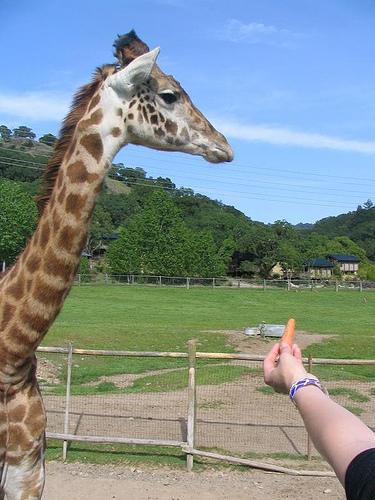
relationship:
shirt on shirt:
[345, 447, 375, 500] [347, 444, 374, 495]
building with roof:
[303, 256, 335, 277] [302, 252, 359, 264]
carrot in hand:
[277, 317, 304, 352] [260, 338, 305, 390]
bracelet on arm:
[289, 377, 329, 402] [264, 341, 373, 495]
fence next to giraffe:
[34, 345, 374, 476] [3, 22, 240, 498]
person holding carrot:
[259, 342, 374, 498] [276, 312, 299, 348]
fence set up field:
[162, 261, 374, 295] [67, 284, 375, 438]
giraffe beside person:
[3, 22, 240, 498] [256, 312, 374, 498]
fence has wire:
[35, 344, 374, 469] [75, 358, 179, 434]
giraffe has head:
[3, 22, 240, 498] [99, 29, 237, 177]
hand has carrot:
[259, 328, 374, 458] [278, 315, 296, 347]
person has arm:
[263, 343, 375, 499] [254, 312, 357, 493]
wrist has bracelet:
[251, 330, 341, 410] [288, 377, 326, 404]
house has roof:
[303, 252, 331, 285] [305, 252, 332, 268]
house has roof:
[325, 254, 361, 274] [326, 252, 358, 261]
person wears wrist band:
[263, 343, 375, 499] [286, 374, 331, 412]